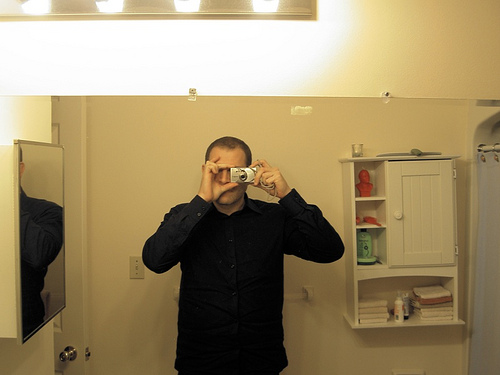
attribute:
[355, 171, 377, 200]
bust — red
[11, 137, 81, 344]
cabinet — mirroed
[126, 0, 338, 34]
light — white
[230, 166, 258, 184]
camera — silver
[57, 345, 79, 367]
door knob — shiny, silver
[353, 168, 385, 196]
statue — brick colored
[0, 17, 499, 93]
wall — white 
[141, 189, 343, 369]
shirt — black, long sleeve, button up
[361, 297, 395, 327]
towels — white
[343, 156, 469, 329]
bathroom shelf — white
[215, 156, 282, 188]
camera — grey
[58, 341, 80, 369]
door knob — silver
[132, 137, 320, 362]
guy — wearing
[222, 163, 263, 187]
camera — small, silver, grey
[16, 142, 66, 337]
mirror — smaller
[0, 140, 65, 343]
cabinet — medicine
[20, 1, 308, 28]
row lights — on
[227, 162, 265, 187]
camera — white 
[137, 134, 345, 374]
man — taking, llght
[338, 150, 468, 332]
rack — bathroom, toiletres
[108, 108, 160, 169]
wall — white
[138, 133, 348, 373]
person — taking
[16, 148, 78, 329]
mirror — large